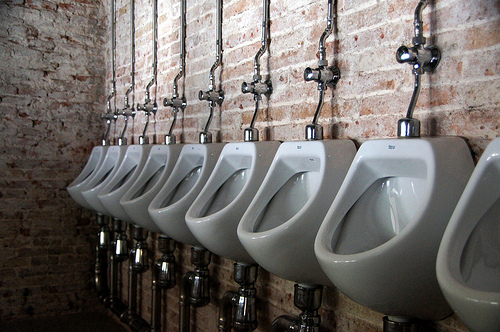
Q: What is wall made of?
A: Bricks.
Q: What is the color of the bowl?
A: White.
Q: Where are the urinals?
A: On the wall.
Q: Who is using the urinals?
A: No one.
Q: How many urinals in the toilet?
A: Nine.